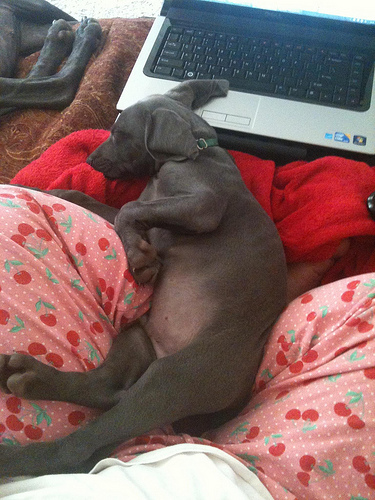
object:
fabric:
[0, 183, 374, 500]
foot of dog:
[0, 348, 38, 399]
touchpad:
[198, 88, 262, 131]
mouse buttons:
[200, 109, 249, 128]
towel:
[10, 127, 373, 283]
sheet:
[1, 443, 274, 500]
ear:
[168, 76, 230, 111]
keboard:
[142, 0, 374, 116]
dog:
[1, 77, 291, 479]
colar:
[196, 137, 218, 151]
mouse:
[365, 191, 375, 220]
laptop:
[115, 0, 374, 168]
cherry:
[98, 237, 117, 260]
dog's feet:
[42, 17, 76, 56]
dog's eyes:
[114, 129, 126, 139]